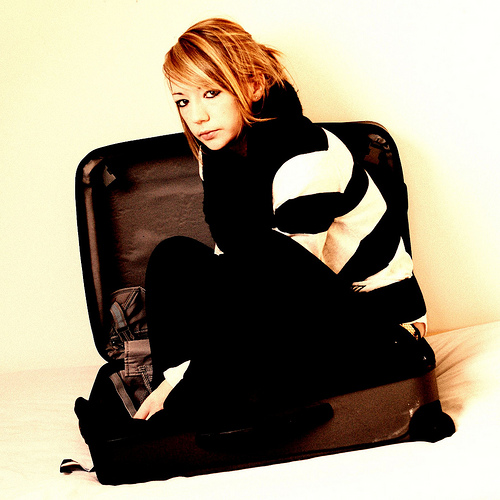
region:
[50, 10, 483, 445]
A person is inside a room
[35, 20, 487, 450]
A person is sitting in a suitcase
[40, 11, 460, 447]
A person is a full grown female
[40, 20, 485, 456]
A person is looking at something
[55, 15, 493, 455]
A person is wearing black pants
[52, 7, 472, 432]
A person is waiting for somebody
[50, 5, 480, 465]
A person is having a good time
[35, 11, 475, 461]
A person is up in the daytime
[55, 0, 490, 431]
A person has red colored hair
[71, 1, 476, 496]
A person is enjoying the day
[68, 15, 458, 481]
girl sitting inside suitcase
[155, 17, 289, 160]
girl has light brown hair with blonde highlights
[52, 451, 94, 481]
tag for the suitcase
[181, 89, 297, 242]
black scarf worn around girl's neck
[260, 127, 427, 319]
part of a cream and black sweater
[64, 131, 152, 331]
part of the inside top part of a suitcase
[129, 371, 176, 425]
hand belonging to girl in suitcase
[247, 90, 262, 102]
small stud earring in left ear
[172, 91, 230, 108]
eyes with black eyeliner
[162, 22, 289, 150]
head of a girl sitting in a suitcase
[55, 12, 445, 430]
a woman sits in a suitcase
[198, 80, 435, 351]
the woman is wearing a sweater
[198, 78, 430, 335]
the sweater is black and white in color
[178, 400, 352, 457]
the suit cases handle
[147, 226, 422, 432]
the woman is wearing black pants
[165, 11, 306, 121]
the woman has highlights in her hair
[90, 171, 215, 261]
the inside of the suitcase is grey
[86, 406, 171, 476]
the outside of the suitcase is black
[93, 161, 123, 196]
one of the suitcases buckle clasps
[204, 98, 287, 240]
the woman's sweater has a big black scarf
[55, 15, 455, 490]
a woman sitting in a suitcase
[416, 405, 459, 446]
the wheel of a suitcase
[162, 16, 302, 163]
a woman with red hair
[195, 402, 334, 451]
the handle of a suitcase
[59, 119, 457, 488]
a black suit case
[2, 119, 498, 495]
a suit case on a bed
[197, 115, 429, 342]
a woman wearing a white striped shirt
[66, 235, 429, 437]
a woman in black pants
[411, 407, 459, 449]
a black wheel on a suitcase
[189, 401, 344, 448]
a black handle for a suitcase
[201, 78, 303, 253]
black scarf on the woman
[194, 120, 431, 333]
black and white striped shirt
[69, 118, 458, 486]
black suitcase on the bed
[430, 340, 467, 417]
wrinkles in the white blanket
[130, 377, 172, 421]
woman's hand in the suitcase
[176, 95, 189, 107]
black eyeliner around the woman's eye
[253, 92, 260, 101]
earring in the woman's ear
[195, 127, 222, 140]
lips on the woman's face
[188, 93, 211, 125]
nose on the woman's face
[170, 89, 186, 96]
eyebrow on the woman's face